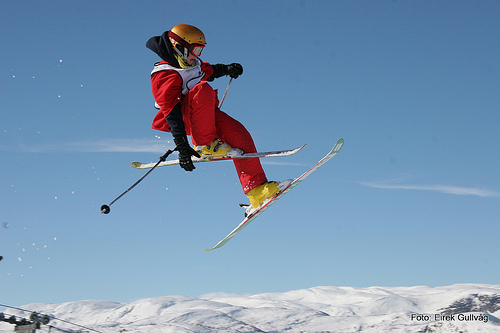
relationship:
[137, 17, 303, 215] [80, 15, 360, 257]
skier doing trick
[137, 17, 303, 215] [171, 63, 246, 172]
skier wearing gloves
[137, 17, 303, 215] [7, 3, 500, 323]
skier floating in air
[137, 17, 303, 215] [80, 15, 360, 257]
skier doing ski jump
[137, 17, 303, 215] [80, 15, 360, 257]
skier hanging in mid air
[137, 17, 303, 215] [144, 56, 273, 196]
skier dressed in red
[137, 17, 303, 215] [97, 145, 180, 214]
person has pole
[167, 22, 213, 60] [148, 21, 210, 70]
helmet on head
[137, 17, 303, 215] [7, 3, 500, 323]
skiier up in air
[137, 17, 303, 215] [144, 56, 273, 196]
skiier wearing snowsuit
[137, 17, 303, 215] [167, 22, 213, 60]
person wearing helmet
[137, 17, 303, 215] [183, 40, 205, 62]
person wearing goggles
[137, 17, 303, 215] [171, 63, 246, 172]
person wearing gloves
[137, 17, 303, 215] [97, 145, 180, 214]
person wearing pole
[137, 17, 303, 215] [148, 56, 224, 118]
person wearing sweatshirt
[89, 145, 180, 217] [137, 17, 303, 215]
pole held by skiier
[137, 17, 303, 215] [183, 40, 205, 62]
skiier worn goggles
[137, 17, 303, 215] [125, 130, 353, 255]
skiier worn ski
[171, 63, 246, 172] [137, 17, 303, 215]
glove worn by skiier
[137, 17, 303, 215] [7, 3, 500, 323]
skiier flying through air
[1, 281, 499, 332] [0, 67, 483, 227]
mountains in distance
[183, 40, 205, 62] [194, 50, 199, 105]
goggles over skiiers face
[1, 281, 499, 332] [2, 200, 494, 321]
snow on ground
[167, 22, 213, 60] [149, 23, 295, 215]
helmet worn by a skier